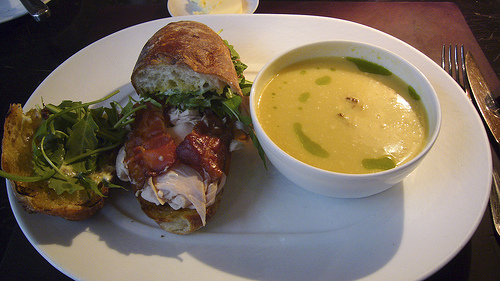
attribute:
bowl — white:
[406, 65, 449, 111]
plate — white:
[436, 172, 483, 241]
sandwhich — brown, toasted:
[81, 37, 223, 237]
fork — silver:
[442, 37, 471, 76]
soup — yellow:
[322, 77, 381, 128]